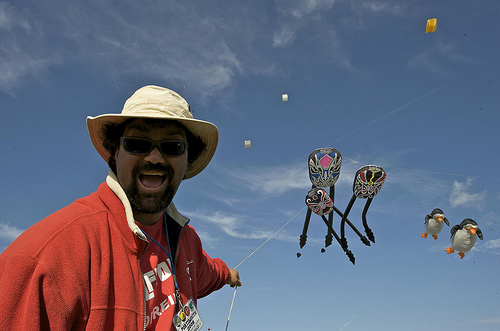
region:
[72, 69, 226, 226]
A man wearing a cream hat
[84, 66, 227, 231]
A man smiling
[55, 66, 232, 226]
A man wearing a cream hat and sunglasses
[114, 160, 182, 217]
A man with a beard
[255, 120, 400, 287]
Blown up kites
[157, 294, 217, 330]
ID tag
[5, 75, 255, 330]
A man wearing a red sweatshirt and t-shit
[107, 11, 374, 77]
Clear skies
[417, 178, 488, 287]
Two penguin kites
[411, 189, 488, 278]
Two penguin kites in the sky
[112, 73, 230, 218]
the head of a man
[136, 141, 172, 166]
the nose of a man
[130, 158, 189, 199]
the mouth of a man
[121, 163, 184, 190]
the teeth of a man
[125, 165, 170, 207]
the tongue of a man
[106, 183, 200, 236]
the chin of a man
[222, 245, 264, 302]
the hand of a man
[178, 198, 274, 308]
the arm of a man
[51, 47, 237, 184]
a man wearing a hat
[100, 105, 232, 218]
a man wearing sunglasses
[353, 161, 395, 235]
kite in the sky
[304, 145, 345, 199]
kite in the sky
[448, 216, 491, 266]
kite in the sky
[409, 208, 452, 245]
kite in the sky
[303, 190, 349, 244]
kite in the sky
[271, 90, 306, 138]
kite in the sky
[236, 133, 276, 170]
kite in the sky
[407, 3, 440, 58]
kite in the sky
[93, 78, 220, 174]
hat on the man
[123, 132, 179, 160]
sunglasses on the man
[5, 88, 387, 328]
man flying three mask kites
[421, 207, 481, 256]
two penguin kites in the sky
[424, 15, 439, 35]
yellow kite in the sky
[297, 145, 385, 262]
three mask kites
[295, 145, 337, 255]
the large blue and pink kite on the left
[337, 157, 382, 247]
the red and black mast on the right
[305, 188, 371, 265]
the small mask in the front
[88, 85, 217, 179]
the man's tan hat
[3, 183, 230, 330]
the man's red fleece sweatshirt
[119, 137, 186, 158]
the man's black sunglasses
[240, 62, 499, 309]
some kites in the sky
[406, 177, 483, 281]
these are penguin kites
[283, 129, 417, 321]
Kabuki mask kites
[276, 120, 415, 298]
Japanese themed kites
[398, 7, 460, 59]
a yellow box kite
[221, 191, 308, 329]
the white kite string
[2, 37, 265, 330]
he is wearing a lot of red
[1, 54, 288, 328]
his jacket is red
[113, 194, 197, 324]
his tee shirt is red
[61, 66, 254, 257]
he is wearing a hat and sunglasses